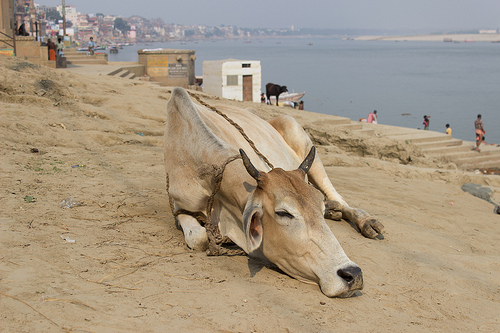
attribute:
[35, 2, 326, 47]
buildings — disance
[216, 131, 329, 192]
horns — dark 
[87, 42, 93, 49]
shirt — light blue  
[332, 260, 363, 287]
nose — black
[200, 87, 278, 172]
fur — brown 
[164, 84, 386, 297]
animal — large 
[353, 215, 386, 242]
hoof — brown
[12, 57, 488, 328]
sand — full 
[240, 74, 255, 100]
door — brown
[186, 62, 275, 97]
building — White 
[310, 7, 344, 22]
clouds — white 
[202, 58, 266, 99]
shack — behind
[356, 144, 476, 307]
sand — golden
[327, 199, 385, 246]
hooves — cloven